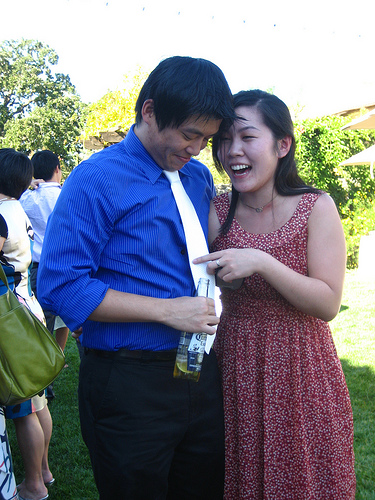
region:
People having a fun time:
[1, 50, 369, 491]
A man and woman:
[74, 62, 355, 495]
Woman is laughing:
[220, 95, 348, 498]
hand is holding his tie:
[201, 246, 258, 278]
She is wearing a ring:
[212, 254, 223, 269]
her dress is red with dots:
[242, 335, 330, 488]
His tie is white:
[166, 171, 210, 252]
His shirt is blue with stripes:
[62, 177, 164, 286]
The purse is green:
[0, 283, 67, 407]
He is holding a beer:
[171, 293, 209, 385]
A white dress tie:
[156, 168, 233, 311]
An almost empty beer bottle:
[166, 274, 219, 381]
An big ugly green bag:
[1, 277, 74, 403]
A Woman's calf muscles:
[13, 403, 63, 467]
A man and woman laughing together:
[32, 48, 373, 498]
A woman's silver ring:
[207, 253, 226, 274]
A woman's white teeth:
[224, 161, 256, 179]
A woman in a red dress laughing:
[210, 90, 346, 498]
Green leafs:
[4, 75, 93, 143]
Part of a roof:
[331, 137, 373, 170]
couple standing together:
[41, 44, 360, 494]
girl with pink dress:
[202, 85, 364, 496]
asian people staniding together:
[35, 48, 358, 495]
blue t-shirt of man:
[37, 132, 227, 367]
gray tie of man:
[159, 171, 223, 340]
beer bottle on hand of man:
[170, 282, 227, 389]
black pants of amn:
[69, 346, 234, 498]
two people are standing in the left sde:
[0, 137, 67, 497]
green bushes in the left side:
[297, 118, 372, 277]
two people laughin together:
[33, 60, 351, 497]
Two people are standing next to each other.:
[32, 52, 353, 496]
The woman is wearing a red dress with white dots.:
[205, 178, 357, 496]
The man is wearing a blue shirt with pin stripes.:
[30, 136, 215, 355]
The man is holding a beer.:
[168, 264, 217, 385]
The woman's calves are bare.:
[10, 405, 62, 497]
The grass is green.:
[56, 405, 74, 485]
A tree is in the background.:
[0, 36, 82, 148]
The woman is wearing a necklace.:
[235, 191, 288, 214]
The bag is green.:
[0, 259, 64, 409]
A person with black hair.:
[26, 139, 65, 187]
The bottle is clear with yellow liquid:
[171, 268, 222, 384]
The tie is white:
[155, 165, 218, 297]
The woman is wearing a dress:
[213, 87, 361, 498]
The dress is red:
[225, 182, 340, 499]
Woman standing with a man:
[49, 47, 362, 465]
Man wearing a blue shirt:
[48, 57, 225, 345]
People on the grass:
[9, 94, 372, 492]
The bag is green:
[0, 272, 74, 411]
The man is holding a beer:
[43, 72, 245, 370]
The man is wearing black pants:
[53, 69, 235, 447]